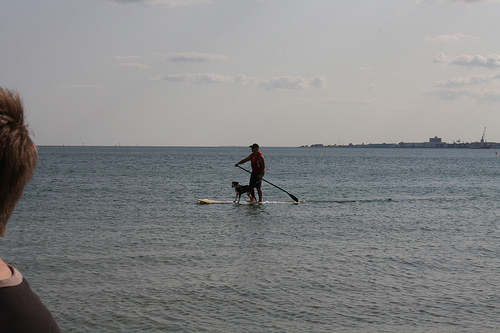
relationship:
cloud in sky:
[415, 28, 498, 108] [3, 2, 488, 148]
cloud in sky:
[102, 27, 333, 91] [3, 2, 488, 148]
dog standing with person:
[231, 176, 255, 206] [233, 143, 266, 203]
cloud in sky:
[167, 50, 222, 65] [29, 1, 496, 139]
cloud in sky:
[263, 73, 307, 95] [29, 1, 496, 139]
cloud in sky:
[153, 68, 220, 93] [29, 1, 496, 139]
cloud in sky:
[438, 50, 498, 69] [29, 1, 496, 139]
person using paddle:
[205, 115, 330, 244] [246, 166, 341, 225]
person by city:
[233, 143, 266, 203] [298, 125, 498, 148]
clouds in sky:
[146, 50, 338, 92] [27, 12, 491, 137]